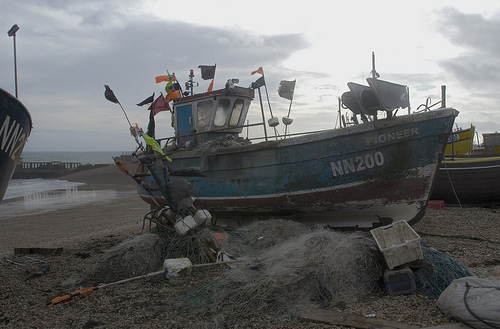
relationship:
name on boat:
[363, 124, 420, 146] [100, 64, 457, 236]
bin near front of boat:
[368, 219, 425, 269] [85, 43, 487, 264]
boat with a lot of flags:
[109, 81, 460, 228] [135, 57, 216, 110]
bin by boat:
[368, 219, 423, 269] [137, 86, 459, 228]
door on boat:
[177, 104, 196, 146] [133, 64, 450, 229]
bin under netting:
[368, 219, 425, 269] [421, 249, 446, 284]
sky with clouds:
[3, 2, 484, 152] [37, 15, 364, 148]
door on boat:
[170, 99, 201, 140] [109, 81, 460, 228]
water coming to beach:
[0, 169, 120, 219] [7, 162, 147, 235]